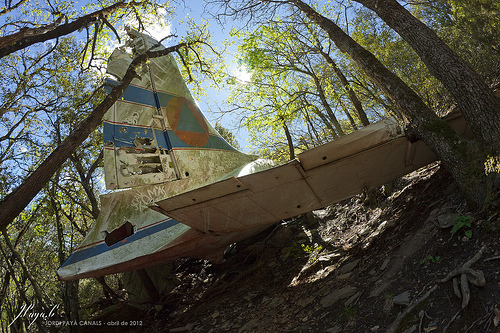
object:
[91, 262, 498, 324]
dirt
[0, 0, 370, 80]
sky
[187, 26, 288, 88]
sun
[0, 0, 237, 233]
trees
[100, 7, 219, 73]
sunlight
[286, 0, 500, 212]
trunks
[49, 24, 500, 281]
wreckage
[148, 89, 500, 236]
wing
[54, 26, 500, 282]
airplane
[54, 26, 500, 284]
plane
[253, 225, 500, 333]
brown dirt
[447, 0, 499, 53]
leaves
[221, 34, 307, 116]
faleaves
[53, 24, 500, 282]
boat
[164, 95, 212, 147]
circle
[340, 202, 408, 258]
patch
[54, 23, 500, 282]
remains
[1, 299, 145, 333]
white letters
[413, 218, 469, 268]
greenery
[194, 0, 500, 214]
trees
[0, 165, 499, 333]
ground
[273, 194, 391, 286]
sun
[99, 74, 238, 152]
young man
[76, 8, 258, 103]
clouds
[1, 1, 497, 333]
woods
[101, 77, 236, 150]
stripes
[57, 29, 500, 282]
airplane tail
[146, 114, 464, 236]
underside